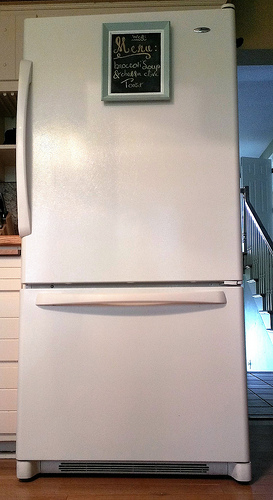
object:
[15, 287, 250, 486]
bottom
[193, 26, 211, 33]
silver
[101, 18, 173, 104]
frame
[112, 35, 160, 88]
sign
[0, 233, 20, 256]
brown counter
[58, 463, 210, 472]
vent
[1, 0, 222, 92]
white cupboard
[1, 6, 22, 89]
shelf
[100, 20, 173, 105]
board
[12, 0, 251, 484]
fridge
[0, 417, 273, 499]
floor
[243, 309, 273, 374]
light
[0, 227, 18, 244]
table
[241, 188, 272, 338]
stairs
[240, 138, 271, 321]
railing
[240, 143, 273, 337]
rail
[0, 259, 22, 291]
drawer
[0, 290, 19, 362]
drawer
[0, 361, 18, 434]
drawer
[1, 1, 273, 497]
kitchen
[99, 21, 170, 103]
menu magnet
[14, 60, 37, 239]
handle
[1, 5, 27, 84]
cabinet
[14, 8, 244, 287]
door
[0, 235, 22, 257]
counter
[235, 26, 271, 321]
room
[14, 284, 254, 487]
freezer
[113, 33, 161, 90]
writing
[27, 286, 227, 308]
handle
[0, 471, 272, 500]
wood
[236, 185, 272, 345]
steps